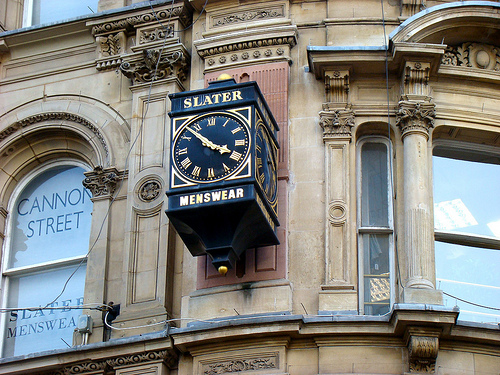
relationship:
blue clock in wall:
[168, 87, 252, 178] [166, 0, 321, 346]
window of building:
[347, 111, 404, 316] [7, 19, 481, 372]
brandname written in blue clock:
[164, 83, 264, 109] [168, 87, 252, 178]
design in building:
[375, 44, 447, 367] [7, 19, 481, 372]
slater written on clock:
[174, 82, 262, 112] [167, 94, 262, 216]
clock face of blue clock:
[172, 111, 251, 184] [168, 87, 252, 178]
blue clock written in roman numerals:
[168, 87, 252, 178] [213, 115, 243, 134]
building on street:
[74, 53, 452, 315] [0, 85, 170, 373]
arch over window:
[5, 97, 121, 338] [431, 140, 497, 322]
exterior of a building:
[4, 15, 498, 357] [7, 19, 481, 372]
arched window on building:
[2, 158, 93, 363] [7, 19, 481, 372]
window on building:
[347, 111, 404, 316] [7, 19, 481, 372]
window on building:
[431, 140, 497, 322] [7, 19, 481, 372]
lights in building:
[440, 161, 486, 279] [7, 19, 481, 372]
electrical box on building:
[73, 314, 93, 349] [7, 19, 481, 372]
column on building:
[385, 39, 462, 328] [7, 19, 481, 372]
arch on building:
[385, 1, 499, 72] [7, 19, 481, 372]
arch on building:
[5, 97, 121, 338] [7, 19, 481, 372]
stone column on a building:
[310, 26, 372, 320] [271, 16, 493, 372]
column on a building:
[385, 39, 462, 328] [7, 19, 481, 372]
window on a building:
[347, 111, 404, 316] [7, 19, 481, 372]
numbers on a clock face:
[175, 116, 243, 176] [172, 111, 251, 184]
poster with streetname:
[9, 171, 96, 361] [8, 179, 93, 262]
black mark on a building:
[221, 277, 267, 303] [0, 0, 500, 375]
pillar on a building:
[1, 0, 498, 373] [318, 66, 360, 317]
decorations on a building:
[202, 8, 289, 65] [7, 19, 481, 372]